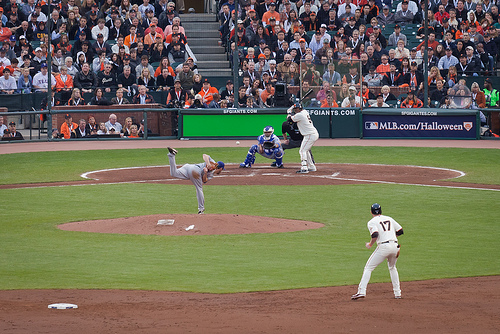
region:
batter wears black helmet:
[285, 99, 306, 111]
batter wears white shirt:
[292, 106, 315, 143]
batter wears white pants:
[285, 129, 315, 177]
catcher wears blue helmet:
[255, 125, 275, 134]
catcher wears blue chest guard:
[255, 126, 280, 161]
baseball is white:
[230, 135, 247, 149]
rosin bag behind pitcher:
[148, 216, 195, 231]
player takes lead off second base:
[355, 199, 415, 286]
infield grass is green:
[178, 215, 345, 267]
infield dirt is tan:
[124, 189, 239, 256]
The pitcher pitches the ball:
[152, 135, 237, 207]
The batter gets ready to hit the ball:
[260, 75, 393, 232]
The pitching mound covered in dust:
[66, 172, 405, 277]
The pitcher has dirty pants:
[162, 137, 229, 220]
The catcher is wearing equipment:
[231, 97, 293, 185]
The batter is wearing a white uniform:
[287, 97, 333, 192]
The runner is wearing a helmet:
[369, 193, 386, 216]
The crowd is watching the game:
[42, 11, 129, 105]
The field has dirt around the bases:
[102, 280, 214, 332]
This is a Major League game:
[355, 96, 484, 191]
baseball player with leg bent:
[163, 138, 226, 215]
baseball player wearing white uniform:
[346, 193, 408, 303]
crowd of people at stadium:
[5, 3, 487, 103]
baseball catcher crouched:
[240, 121, 290, 171]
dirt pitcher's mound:
[53, 208, 333, 240]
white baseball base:
[43, 297, 80, 311]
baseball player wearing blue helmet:
[351, 196, 406, 306]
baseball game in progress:
[110, 86, 409, 303]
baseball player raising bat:
[278, 76, 328, 177]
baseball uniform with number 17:
[347, 193, 406, 300]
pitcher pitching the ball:
[102, 117, 249, 266]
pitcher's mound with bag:
[89, 193, 308, 264]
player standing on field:
[352, 190, 424, 330]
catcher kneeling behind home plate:
[234, 113, 317, 198]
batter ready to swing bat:
[271, 76, 346, 193]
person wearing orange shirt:
[194, 75, 221, 110]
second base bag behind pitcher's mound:
[19, 192, 256, 318]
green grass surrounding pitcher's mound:
[54, 193, 338, 270]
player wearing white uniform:
[329, 189, 421, 330]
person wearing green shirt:
[467, 65, 499, 125]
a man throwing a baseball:
[150, 140, 226, 216]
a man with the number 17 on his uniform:
[352, 185, 414, 297]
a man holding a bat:
[286, 81, 326, 151]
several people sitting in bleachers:
[258, 19, 462, 99]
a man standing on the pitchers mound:
[129, 142, 234, 257]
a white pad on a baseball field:
[36, 291, 96, 331]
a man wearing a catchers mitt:
[226, 113, 281, 198]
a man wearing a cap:
[193, 77, 212, 99]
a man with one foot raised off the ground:
[145, 145, 231, 204]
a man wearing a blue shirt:
[434, 44, 459, 75]